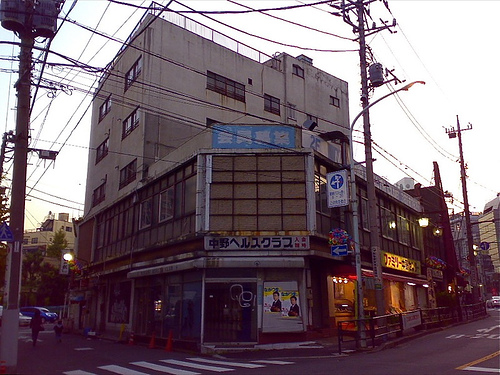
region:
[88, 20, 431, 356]
a building with many widows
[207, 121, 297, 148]
Chinese writing on a blue sign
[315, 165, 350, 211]
a street sign with a blue circle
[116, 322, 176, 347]
three traffic cones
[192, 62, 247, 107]
a long window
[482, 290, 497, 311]
a silver car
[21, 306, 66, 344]
people walking down the street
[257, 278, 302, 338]
a poster on the wall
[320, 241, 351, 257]
a sign with a left arrow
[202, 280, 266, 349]
a door with graffiti on it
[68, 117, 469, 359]
Store in the corner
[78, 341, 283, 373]
Pedestrian passage on corner of street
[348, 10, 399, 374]
Electric pole on sidewalk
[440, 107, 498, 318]
Electrical pole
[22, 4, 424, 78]
Wires on street poles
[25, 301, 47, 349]
Person walking in the street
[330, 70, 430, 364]
Light pole on sidewalk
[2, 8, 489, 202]
Sky is cloudy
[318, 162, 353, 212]
Sign of street on pole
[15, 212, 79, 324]
Buildings on the background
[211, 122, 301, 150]
Board is blue color.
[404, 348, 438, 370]
Road is grey color.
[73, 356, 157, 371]
White lines are in road.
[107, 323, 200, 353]
Orange cones are in sides of road.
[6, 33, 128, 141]
wire lines are passing above the road.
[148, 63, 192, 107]
Building is brown color.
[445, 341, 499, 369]
Yellow lines are marked in the road.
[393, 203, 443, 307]
Lights are on.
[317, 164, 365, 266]
Pole is grey color.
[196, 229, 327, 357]
Store in the corner of street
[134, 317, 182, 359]
Traffic orange cones on street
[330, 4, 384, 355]
High light pole holding electric wires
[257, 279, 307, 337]
Posters on window of store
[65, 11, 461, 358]
Old building in the corner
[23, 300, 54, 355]
Person walking down the street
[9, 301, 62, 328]
Cars parking on side of street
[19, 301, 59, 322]
Blue car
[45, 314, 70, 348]
Child walking with mom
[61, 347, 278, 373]
Crossing line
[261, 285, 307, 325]
white and yellow sign with man in black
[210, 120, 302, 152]
blue sign with white Asian lettering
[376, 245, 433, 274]
yellow sign with red Asian lettering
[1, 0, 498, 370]
brown wooden poles with electrical wires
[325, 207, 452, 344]
lights lining side of building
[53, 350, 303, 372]
painted white crosswalk lines on pavement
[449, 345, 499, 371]
yellow painted line on street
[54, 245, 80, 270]
lit lamp hanging from building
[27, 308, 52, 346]
silhouette of person walking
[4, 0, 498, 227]
clear white sky above building